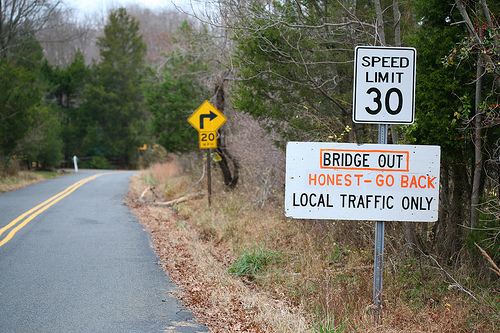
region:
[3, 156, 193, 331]
Small road in the countryside.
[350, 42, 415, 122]
White road sign with black writting.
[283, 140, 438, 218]
White road sign with black and orange writting.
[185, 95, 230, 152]
Yellow road sign on the road.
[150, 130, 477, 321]
Road side is bushy.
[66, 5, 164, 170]
Tall green pin tree in the near background.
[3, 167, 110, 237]
Yellow lines across the road.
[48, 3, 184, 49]
Leafless grey trees in the far background.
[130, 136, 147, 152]
Hidden yellow road sign down the road.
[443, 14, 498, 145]
Leaves of different colors.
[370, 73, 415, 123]
part of a number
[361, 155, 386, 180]
part of a board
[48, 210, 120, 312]
part of a floor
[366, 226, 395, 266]
part of a post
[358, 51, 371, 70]
The letter is black.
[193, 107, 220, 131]
The arrow is black.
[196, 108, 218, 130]
The arrow is pointing right.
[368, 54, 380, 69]
The letter is black.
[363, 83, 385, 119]
The number is black.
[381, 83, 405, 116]
The numbr is black.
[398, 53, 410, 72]
The letter is black.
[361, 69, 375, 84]
The letter is black.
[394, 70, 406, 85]
The letter is black.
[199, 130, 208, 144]
The numbr is black.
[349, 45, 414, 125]
speed limit sign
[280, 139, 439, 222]
warning sign of a bridge being out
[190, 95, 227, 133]
yellow sign telling the road will turn right ahead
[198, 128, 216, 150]
a suggested speed limit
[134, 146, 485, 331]
grass is long and dried out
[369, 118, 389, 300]
metal pole to mount signs to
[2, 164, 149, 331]
a roah with a double yellow line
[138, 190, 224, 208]
a downed log on the side of the road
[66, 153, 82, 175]
a mail box on the road side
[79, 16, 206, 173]
evergreen trees at the turn in the road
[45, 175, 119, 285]
this is a road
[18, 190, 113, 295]
the road is tarmacked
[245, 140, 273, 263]
these are the grass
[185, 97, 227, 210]
this is a post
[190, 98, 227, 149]
the post is yellow in color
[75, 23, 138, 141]
this is a tree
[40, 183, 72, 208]
yellow strips are in the middle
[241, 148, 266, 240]
the grass are dry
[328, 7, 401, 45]
the tree is dry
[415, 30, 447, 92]
the leaves are green in color